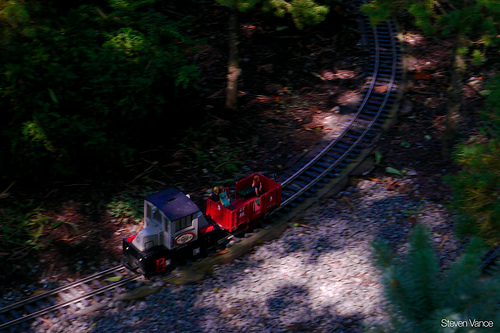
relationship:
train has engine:
[119, 165, 293, 269] [126, 186, 219, 278]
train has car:
[119, 165, 293, 269] [207, 173, 284, 238]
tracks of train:
[5, 7, 428, 330] [119, 165, 293, 269]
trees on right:
[405, 6, 499, 330] [452, 6, 498, 331]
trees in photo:
[405, 6, 499, 330] [2, 4, 499, 332]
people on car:
[212, 174, 268, 206] [207, 173, 284, 238]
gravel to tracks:
[244, 243, 385, 312] [5, 7, 428, 330]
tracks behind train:
[5, 7, 428, 330] [119, 165, 293, 269]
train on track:
[119, 165, 293, 269] [5, 7, 428, 330]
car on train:
[207, 173, 284, 238] [119, 165, 293, 269]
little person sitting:
[244, 175, 266, 198] [246, 179, 267, 196]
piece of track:
[212, 225, 267, 248] [5, 7, 428, 330]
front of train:
[111, 214, 172, 283] [119, 165, 293, 269]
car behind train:
[207, 173, 284, 238] [119, 165, 293, 269]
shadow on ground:
[203, 30, 358, 138] [83, 25, 461, 135]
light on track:
[54, 277, 94, 319] [5, 7, 428, 330]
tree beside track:
[215, 3, 263, 115] [5, 7, 428, 330]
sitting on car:
[246, 179, 267, 196] [207, 173, 284, 238]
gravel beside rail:
[244, 243, 385, 312] [281, 19, 407, 204]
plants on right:
[405, 6, 499, 330] [452, 6, 498, 331]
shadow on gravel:
[203, 30, 358, 138] [244, 243, 385, 312]